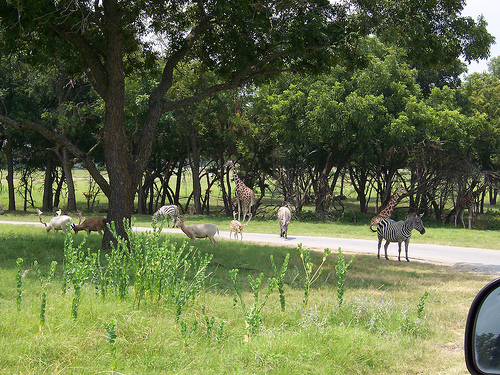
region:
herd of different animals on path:
[17, 147, 431, 253]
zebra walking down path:
[362, 208, 427, 264]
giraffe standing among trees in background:
[215, 158, 257, 221]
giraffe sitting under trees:
[363, 178, 410, 224]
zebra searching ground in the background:
[144, 199, 179, 233]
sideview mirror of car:
[452, 283, 499, 373]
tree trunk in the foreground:
[15, 79, 219, 235]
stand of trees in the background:
[11, 83, 476, 213]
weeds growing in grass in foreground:
[8, 212, 364, 345]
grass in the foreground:
[4, 220, 462, 365]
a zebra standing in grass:
[368, 211, 428, 262]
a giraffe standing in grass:
[220, 159, 256, 225]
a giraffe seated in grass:
[368, 185, 408, 224]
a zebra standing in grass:
[148, 205, 182, 227]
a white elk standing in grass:
[35, 202, 72, 235]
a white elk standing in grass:
[64, 208, 105, 237]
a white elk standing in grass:
[170, 205, 219, 245]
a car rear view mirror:
[463, 274, 497, 374]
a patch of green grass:
[0, 221, 495, 373]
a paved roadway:
[0, 220, 499, 277]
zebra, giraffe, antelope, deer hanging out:
[22, 150, 449, 270]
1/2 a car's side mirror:
[456, 276, 498, 373]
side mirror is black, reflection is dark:
[461, 275, 498, 372]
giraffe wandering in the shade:
[437, 171, 498, 240]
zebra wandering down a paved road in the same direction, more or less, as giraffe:
[363, 209, 433, 269]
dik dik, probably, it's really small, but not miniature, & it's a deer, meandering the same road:
[221, 216, 245, 241]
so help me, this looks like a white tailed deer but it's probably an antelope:
[169, 215, 224, 249]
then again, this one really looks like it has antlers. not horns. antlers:
[29, 207, 73, 241]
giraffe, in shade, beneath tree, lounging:
[356, 182, 412, 236]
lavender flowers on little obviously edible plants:
[280, 290, 407, 347]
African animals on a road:
[2, 173, 464, 270]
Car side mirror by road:
[446, 245, 498, 372]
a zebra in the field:
[375, 210, 430, 258]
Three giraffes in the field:
[207, 151, 498, 232]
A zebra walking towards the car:
[265, 191, 305, 246]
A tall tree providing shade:
[3, 3, 490, 244]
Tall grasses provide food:
[11, 221, 441, 367]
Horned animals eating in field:
[30, 199, 256, 252]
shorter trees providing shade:
[1, 24, 495, 229]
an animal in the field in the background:
[75, 184, 102, 206]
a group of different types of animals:
[12, 153, 449, 274]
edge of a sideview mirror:
[449, 277, 496, 374]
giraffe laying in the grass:
[359, 175, 411, 235]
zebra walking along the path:
[366, 215, 436, 265]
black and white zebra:
[144, 200, 179, 230]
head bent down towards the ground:
[148, 210, 160, 231]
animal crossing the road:
[269, 196, 300, 241]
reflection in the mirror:
[474, 328, 499, 370]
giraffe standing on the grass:
[222, 163, 264, 227]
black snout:
[419, 228, 424, 234]